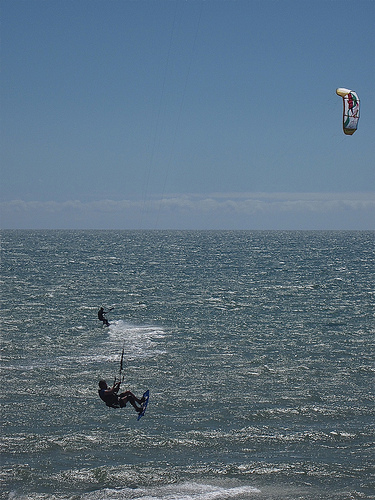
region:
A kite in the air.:
[335, 84, 360, 136]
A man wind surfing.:
[92, 379, 148, 420]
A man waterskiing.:
[95, 306, 112, 329]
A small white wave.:
[108, 320, 123, 332]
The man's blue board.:
[136, 388, 149, 422]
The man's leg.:
[123, 395, 141, 412]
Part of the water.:
[274, 339, 317, 380]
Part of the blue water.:
[102, 244, 141, 269]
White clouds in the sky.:
[171, 194, 227, 213]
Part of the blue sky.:
[60, 145, 127, 183]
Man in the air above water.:
[92, 374, 153, 425]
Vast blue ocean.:
[1, 230, 370, 491]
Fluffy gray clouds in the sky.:
[3, 189, 372, 219]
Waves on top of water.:
[167, 299, 365, 491]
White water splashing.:
[100, 315, 155, 347]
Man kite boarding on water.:
[95, 301, 119, 331]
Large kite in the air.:
[332, 82, 363, 139]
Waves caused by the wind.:
[12, 244, 341, 469]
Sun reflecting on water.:
[20, 418, 323, 493]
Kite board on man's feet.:
[134, 391, 150, 423]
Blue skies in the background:
[70, 33, 123, 63]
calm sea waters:
[211, 269, 309, 318]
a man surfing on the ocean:
[96, 380, 152, 413]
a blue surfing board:
[138, 389, 149, 421]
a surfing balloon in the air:
[336, 88, 362, 138]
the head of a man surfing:
[97, 381, 106, 389]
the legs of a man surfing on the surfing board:
[124, 388, 149, 416]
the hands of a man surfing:
[113, 382, 119, 391]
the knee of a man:
[126, 393, 132, 398]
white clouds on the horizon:
[163, 198, 209, 215]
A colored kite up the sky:
[325, 68, 358, 137]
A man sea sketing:
[100, 369, 156, 414]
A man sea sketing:
[92, 299, 116, 328]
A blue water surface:
[231, 408, 348, 466]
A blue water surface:
[263, 336, 364, 397]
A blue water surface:
[225, 238, 348, 322]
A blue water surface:
[105, 257, 207, 323]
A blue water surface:
[102, 222, 210, 269]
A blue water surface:
[19, 403, 102, 469]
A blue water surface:
[4, 298, 74, 386]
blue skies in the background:
[81, 43, 183, 101]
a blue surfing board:
[135, 387, 145, 417]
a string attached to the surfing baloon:
[116, 330, 131, 362]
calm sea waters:
[152, 227, 328, 302]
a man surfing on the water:
[92, 303, 111, 325]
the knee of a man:
[122, 393, 131, 397]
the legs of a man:
[126, 390, 141, 408]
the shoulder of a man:
[96, 390, 106, 394]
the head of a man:
[99, 381, 109, 390]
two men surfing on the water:
[94, 300, 152, 415]